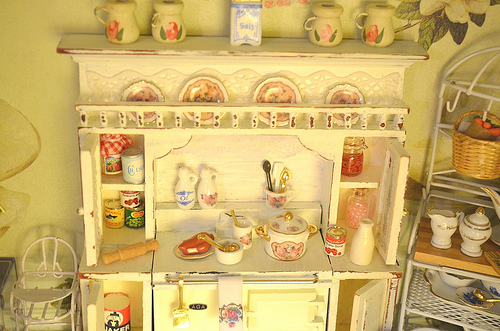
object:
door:
[347, 275, 388, 329]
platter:
[421, 267, 498, 322]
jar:
[342, 138, 365, 174]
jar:
[464, 203, 491, 255]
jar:
[103, 132, 122, 172]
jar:
[347, 186, 374, 228]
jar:
[171, 162, 196, 205]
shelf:
[337, 215, 378, 229]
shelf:
[341, 172, 387, 185]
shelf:
[158, 197, 321, 210]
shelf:
[416, 246, 493, 268]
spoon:
[261, 158, 271, 193]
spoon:
[274, 158, 281, 185]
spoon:
[281, 168, 288, 191]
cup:
[261, 186, 294, 208]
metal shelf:
[393, 44, 499, 329]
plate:
[322, 71, 371, 130]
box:
[88, 281, 137, 322]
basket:
[450, 134, 497, 181]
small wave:
[65, 40, 437, 330]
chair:
[14, 230, 81, 330]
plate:
[176, 77, 230, 126]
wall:
[0, 98, 184, 218]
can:
[125, 205, 147, 230]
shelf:
[91, 130, 151, 192]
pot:
[252, 207, 320, 261]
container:
[203, 0, 288, 59]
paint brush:
[169, 277, 191, 328]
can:
[326, 227, 345, 255]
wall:
[20, 25, 57, 107]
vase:
[346, 214, 381, 269]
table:
[38, 23, 420, 328]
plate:
[250, 73, 301, 125]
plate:
[124, 80, 164, 122]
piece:
[256, 210, 320, 262]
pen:
[98, 217, 170, 283]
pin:
[99, 236, 159, 265]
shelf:
[83, 102, 418, 137]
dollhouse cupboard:
[50, 28, 415, 329]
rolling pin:
[98, 236, 159, 266]